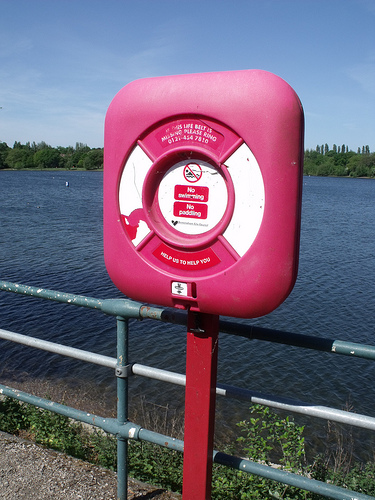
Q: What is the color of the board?
A: Red.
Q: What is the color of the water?
A: Blue.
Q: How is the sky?
A: Clear.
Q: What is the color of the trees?
A: Green.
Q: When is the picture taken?
A: Daytime.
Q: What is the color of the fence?
A: Grey.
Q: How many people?
A: No one.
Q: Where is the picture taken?
A: Close to the lake.